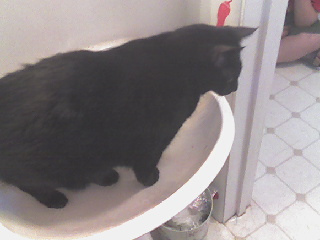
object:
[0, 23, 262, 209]
cat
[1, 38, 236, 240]
sink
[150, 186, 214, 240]
bin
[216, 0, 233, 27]
pepper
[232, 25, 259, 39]
ear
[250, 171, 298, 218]
tile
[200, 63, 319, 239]
floor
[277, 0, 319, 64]
chair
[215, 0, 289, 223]
jam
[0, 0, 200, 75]
wall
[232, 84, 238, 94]
nose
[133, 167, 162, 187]
paw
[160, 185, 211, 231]
bag